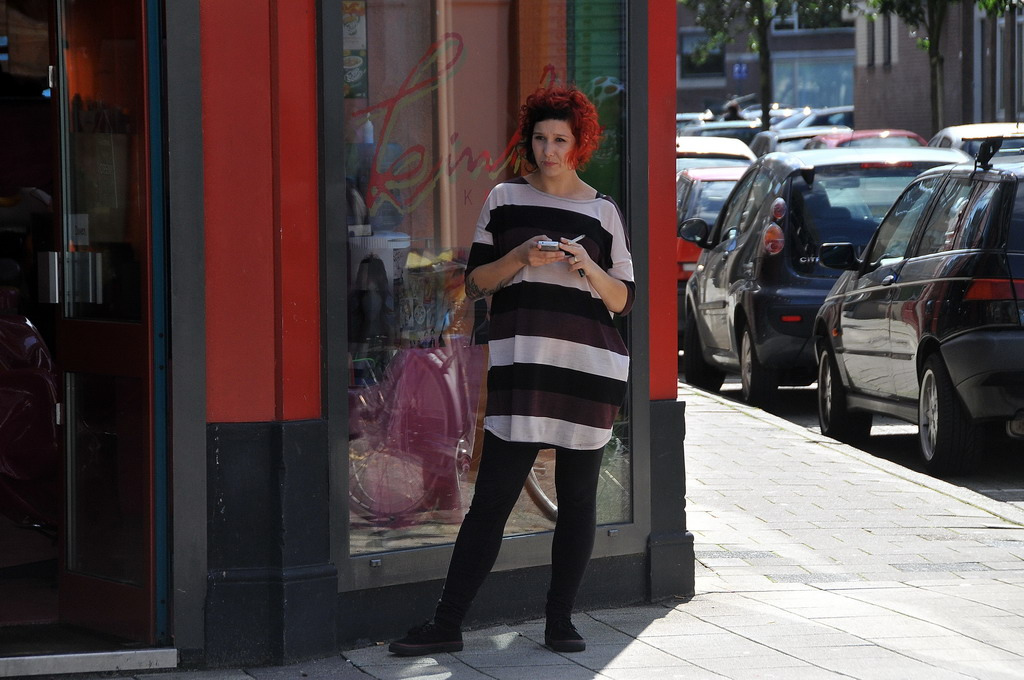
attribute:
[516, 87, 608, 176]
hair — red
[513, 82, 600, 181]
hair — red, black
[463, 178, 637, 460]
shirt — striped, black, white, brown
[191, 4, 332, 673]
building exterior — red, black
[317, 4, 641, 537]
window — glass